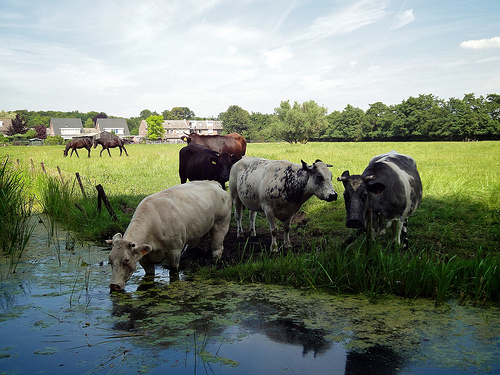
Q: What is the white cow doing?
A: Drinking water.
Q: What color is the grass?
A: Green.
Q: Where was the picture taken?
A: At a watering hole.